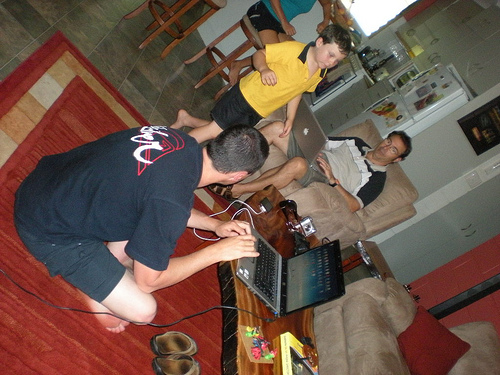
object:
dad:
[204, 121, 413, 213]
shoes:
[148, 331, 200, 359]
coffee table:
[216, 183, 324, 373]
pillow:
[395, 306, 472, 374]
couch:
[310, 275, 498, 374]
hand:
[213, 234, 260, 263]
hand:
[212, 219, 254, 239]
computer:
[290, 103, 331, 176]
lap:
[278, 155, 312, 176]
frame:
[455, 95, 500, 157]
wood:
[123, 0, 229, 60]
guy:
[12, 123, 270, 336]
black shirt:
[13, 124, 207, 303]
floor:
[2, 0, 376, 374]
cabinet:
[396, 0, 500, 96]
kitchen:
[121, 0, 498, 205]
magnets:
[410, 85, 432, 100]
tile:
[58, 0, 118, 51]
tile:
[114, 78, 155, 124]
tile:
[153, 81, 192, 133]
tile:
[124, 64, 162, 108]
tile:
[86, 47, 128, 93]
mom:
[224, 0, 333, 86]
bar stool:
[181, 14, 266, 89]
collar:
[296, 41, 328, 80]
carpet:
[0, 31, 241, 374]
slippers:
[149, 354, 204, 373]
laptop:
[232, 227, 347, 320]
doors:
[395, 62, 464, 124]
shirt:
[236, 40, 326, 119]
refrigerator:
[323, 63, 470, 139]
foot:
[84, 294, 131, 336]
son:
[167, 24, 354, 144]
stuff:
[410, 92, 442, 113]